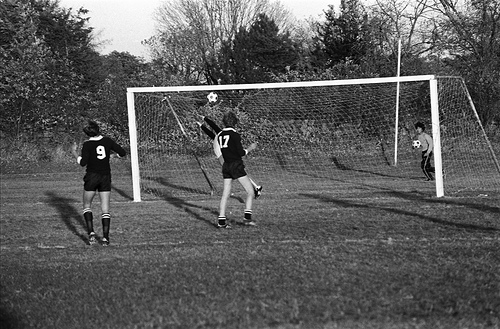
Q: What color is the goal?
A: White.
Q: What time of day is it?
A: Day time.